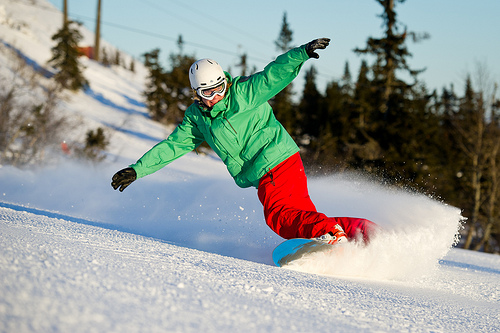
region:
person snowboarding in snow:
[70, 23, 455, 298]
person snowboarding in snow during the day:
[35, 25, 450, 313]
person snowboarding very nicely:
[95, 27, 430, 292]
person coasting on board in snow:
[102, 23, 419, 305]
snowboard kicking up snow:
[261, 176, 480, 301]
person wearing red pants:
[242, 148, 380, 262]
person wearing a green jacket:
[144, 23, 323, 183]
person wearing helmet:
[183, 53, 240, 110]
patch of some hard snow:
[40, 243, 295, 319]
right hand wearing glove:
[92, 167, 158, 205]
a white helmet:
[191, 62, 226, 91]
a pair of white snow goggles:
[196, 80, 230, 99]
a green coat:
[188, 107, 312, 175]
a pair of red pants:
[260, 166, 357, 245]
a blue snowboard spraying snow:
[272, 240, 392, 282]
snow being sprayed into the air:
[159, 182, 231, 247]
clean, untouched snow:
[42, 239, 141, 328]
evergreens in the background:
[362, 27, 492, 192]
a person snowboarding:
[152, 30, 407, 313]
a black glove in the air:
[305, 37, 329, 59]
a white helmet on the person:
[183, 53, 227, 88]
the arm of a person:
[252, 43, 308, 101]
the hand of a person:
[300, 30, 331, 65]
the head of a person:
[184, 46, 235, 117]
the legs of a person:
[249, 151, 344, 240]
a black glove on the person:
[108, 157, 139, 193]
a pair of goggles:
[194, 75, 234, 101]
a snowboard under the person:
[266, 229, 379, 272]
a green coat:
[128, 36, 314, 190]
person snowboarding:
[87, 36, 425, 291]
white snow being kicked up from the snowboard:
[291, 208, 467, 285]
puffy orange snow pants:
[234, 160, 386, 247]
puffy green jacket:
[133, 49, 321, 191]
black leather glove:
[106, 166, 140, 193]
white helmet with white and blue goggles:
[182, 58, 234, 115]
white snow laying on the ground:
[7, 221, 498, 329]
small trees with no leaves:
[3, 72, 115, 169]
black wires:
[103, 0, 282, 58]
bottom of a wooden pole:
[96, 0, 103, 60]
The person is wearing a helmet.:
[151, 37, 253, 112]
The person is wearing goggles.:
[170, 52, 249, 114]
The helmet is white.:
[165, 52, 243, 115]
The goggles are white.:
[169, 52, 237, 110]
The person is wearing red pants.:
[242, 140, 397, 258]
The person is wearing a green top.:
[104, 34, 331, 208]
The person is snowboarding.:
[96, 24, 404, 283]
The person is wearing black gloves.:
[86, 145, 153, 205]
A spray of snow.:
[304, 155, 479, 290]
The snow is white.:
[26, 229, 200, 320]